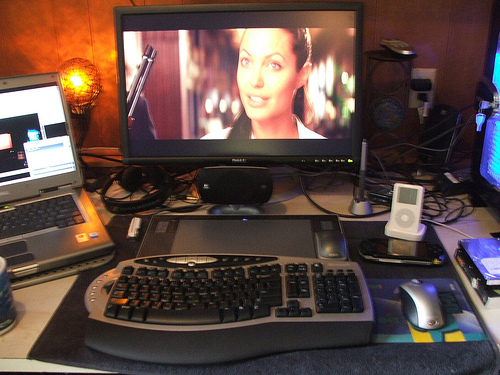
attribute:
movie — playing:
[122, 14, 353, 153]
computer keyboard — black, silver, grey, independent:
[99, 252, 373, 354]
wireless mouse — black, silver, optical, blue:
[392, 278, 449, 337]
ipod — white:
[386, 180, 423, 230]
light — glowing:
[60, 50, 103, 100]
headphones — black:
[100, 161, 171, 209]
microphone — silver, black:
[349, 139, 374, 219]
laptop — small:
[1, 68, 115, 263]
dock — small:
[380, 231, 429, 244]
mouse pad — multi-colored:
[373, 278, 402, 344]